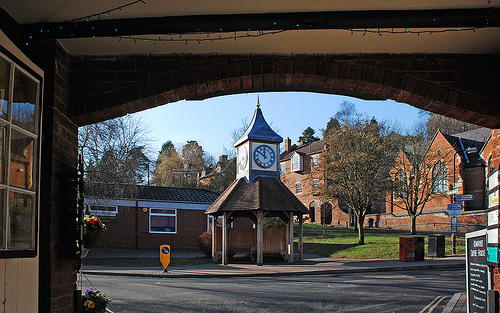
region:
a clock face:
[253, 143, 276, 168]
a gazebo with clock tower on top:
[204, 93, 306, 265]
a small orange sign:
[157, 243, 172, 273]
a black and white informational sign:
[464, 228, 491, 310]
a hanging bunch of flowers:
[83, 214, 103, 251]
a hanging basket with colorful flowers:
[79, 286, 110, 311]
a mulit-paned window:
[1, 29, 41, 257]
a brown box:
[396, 235, 426, 263]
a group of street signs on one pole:
[447, 183, 477, 259]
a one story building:
[82, 181, 228, 253]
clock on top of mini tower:
[254, 144, 281, 176]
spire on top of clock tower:
[255, 94, 276, 121]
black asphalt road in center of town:
[283, 296, 320, 311]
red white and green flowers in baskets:
[83, 209, 114, 249]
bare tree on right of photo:
[401, 153, 461, 212]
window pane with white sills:
[0, 184, 37, 264]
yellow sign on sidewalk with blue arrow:
[156, 239, 178, 276]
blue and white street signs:
[444, 191, 467, 231]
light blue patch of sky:
[185, 112, 217, 139]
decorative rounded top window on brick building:
[429, 161, 463, 202]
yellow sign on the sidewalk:
[156, 240, 171, 271]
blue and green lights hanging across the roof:
[10, 3, 335, 52]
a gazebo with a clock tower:
[199, 106, 319, 268]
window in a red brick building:
[146, 205, 183, 234]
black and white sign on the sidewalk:
[457, 228, 487, 308]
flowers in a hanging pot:
[79, 203, 109, 255]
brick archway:
[67, 60, 493, 131]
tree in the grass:
[322, 122, 390, 248]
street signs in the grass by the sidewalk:
[440, 189, 480, 254]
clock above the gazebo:
[249, 142, 279, 169]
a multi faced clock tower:
[234, 98, 282, 180]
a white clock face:
[250, 143, 274, 165]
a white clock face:
[237, 143, 247, 168]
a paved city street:
[80, 259, 470, 311]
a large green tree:
[312, 119, 399, 242]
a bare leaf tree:
[386, 136, 447, 233]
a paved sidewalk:
[82, 254, 469, 276]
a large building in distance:
[275, 133, 363, 226]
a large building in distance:
[370, 127, 498, 232]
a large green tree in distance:
[148, 138, 184, 186]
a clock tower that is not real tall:
[224, 97, 286, 193]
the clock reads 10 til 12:
[244, 135, 280, 173]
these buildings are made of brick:
[299, 168, 448, 229]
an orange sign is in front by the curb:
[160, 239, 177, 281]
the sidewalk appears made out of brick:
[133, 247, 346, 279]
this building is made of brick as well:
[101, 75, 453, 106]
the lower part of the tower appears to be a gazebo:
[215, 178, 324, 274]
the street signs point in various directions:
[445, 171, 477, 234]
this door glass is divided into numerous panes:
[0, 55, 57, 312]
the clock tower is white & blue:
[232, 101, 294, 183]